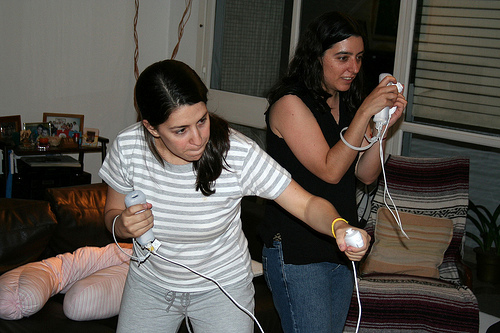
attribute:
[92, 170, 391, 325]
remote controls — for electronic game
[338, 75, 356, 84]
mouth — smiling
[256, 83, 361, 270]
shirt — black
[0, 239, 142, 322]
pillow — pink and white, on couch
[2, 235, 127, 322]
pillows — pink, white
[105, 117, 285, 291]
shirt — striped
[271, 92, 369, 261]
shirt — black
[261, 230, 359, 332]
jeans — blue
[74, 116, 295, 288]
shirt — grey, white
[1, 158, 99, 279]
sofa — brown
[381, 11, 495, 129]
blinds — cream